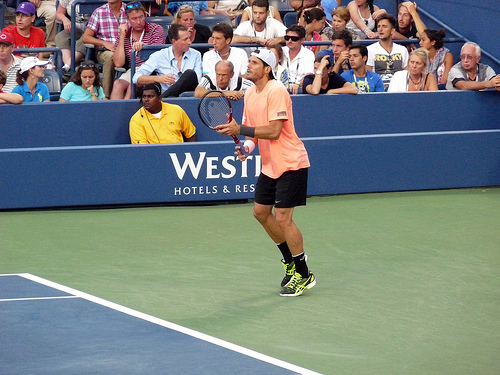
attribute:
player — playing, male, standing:
[199, 44, 319, 300]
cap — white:
[249, 43, 285, 78]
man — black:
[123, 78, 203, 143]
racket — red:
[191, 81, 251, 160]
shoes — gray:
[280, 265, 320, 299]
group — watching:
[0, 1, 499, 91]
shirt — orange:
[236, 80, 306, 182]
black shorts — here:
[245, 157, 317, 218]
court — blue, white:
[4, 205, 467, 375]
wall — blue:
[0, 123, 493, 215]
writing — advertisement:
[165, 144, 260, 205]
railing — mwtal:
[421, 6, 497, 69]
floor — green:
[12, 200, 495, 365]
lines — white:
[4, 265, 310, 372]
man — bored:
[444, 26, 497, 97]